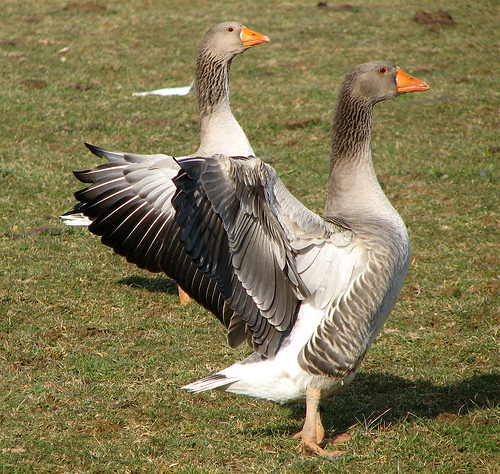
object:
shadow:
[235, 366, 499, 456]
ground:
[2, 3, 483, 470]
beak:
[395, 71, 429, 94]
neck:
[333, 78, 371, 183]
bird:
[58, 58, 427, 458]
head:
[333, 58, 429, 112]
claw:
[302, 433, 345, 462]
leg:
[295, 384, 331, 458]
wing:
[162, 154, 314, 357]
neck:
[194, 49, 233, 122]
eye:
[227, 24, 234, 34]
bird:
[57, 22, 269, 305]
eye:
[375, 67, 389, 74]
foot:
[297, 425, 339, 458]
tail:
[179, 370, 238, 401]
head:
[195, 15, 269, 66]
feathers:
[65, 143, 181, 279]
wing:
[61, 143, 182, 283]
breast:
[366, 186, 411, 337]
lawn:
[0, 4, 499, 469]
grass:
[2, 0, 497, 470]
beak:
[236, 23, 270, 52]